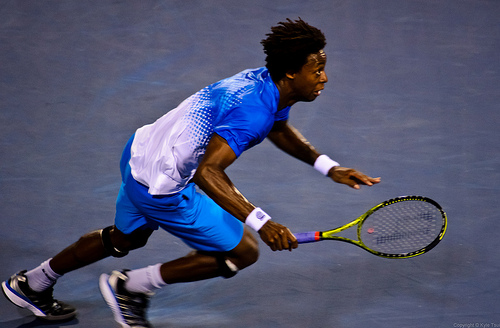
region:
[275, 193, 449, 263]
yellow tennis racket in hand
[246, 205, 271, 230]
white wrist band on wrist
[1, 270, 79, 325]
black sneakers on tennis player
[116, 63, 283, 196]
blue and white shirt on tennis player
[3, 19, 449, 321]
athlete playing a game of tennis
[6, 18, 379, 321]
man wearing blue shorts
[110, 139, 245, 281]
blue shorts on tennis player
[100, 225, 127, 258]
black band on top of calf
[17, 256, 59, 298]
white sock on tennis player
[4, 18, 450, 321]
athlete playing on tennis court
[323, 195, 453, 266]
black and yellow tennis racket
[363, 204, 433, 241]
logo on front of racket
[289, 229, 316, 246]
purple handle to tennis racket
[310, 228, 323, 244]
orange and black handle to racket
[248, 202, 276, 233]
white wrist band on man's arm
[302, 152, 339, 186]
white wrist band on man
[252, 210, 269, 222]
logo on front of wrist band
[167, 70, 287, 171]
blue and white tennis shirt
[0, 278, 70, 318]
black and white tennis shoes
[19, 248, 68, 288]
white and black tennis socks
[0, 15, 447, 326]
the man playing tennis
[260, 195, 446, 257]
the tennis racquet in the man's hand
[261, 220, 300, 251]
the hand holding the racquet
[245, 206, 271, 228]
the wristband on the man's arm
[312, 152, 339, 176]
the wristband on the man's arm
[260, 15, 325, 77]
the hair on the man's head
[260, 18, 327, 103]
the man's head full of hair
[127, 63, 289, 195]
the blue and white shirt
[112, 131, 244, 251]
the man's blue shorts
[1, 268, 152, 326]
the shoes on the man's feet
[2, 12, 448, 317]
tennis player slanted forward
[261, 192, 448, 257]
hand around blue handle of yellow and black racket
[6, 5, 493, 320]
worn blue surface of tennis court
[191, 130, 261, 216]
long muscles along arm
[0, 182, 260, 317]
one leg in front of the other leg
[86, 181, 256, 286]
black bands below bent knees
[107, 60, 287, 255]
player wearing bright blue and white outfit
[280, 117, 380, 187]
arm with wristband extended forward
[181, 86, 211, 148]
blue and white checkerboard across shirt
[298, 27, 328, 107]
face showing deep concentration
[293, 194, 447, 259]
red yellow and black tennis raquet with purple grip wrap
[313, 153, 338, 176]
white elastic cotton sport wrist band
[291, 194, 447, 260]
Prince tennis racquet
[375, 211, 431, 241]
stylized P logo of Prince sporting goods company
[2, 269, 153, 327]
black gold and white pair of tennis shoes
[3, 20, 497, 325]
tennis player in full run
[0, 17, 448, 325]
tennis player runs to set up for shot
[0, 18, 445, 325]
approaching the shot at a dead run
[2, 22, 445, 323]
tennis player pushing off back foot to run to ball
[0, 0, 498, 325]
tennis player in blue and white tennis clothes runs across court